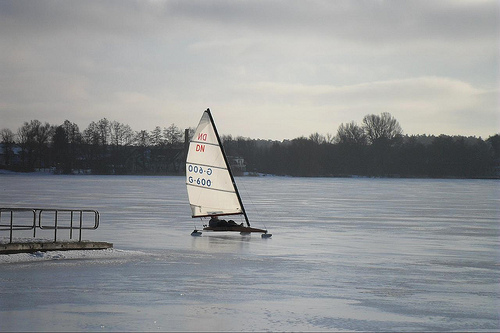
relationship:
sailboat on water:
[176, 106, 272, 243] [2, 170, 499, 332]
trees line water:
[1, 110, 406, 157] [2, 170, 499, 332]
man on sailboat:
[204, 212, 246, 228] [176, 106, 272, 243]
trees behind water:
[1, 110, 406, 157] [2, 170, 499, 332]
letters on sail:
[186, 163, 215, 189] [184, 107, 243, 215]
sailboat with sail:
[176, 106, 272, 243] [184, 107, 243, 215]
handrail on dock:
[0, 207, 102, 239] [1, 208, 113, 256]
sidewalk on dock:
[1, 243, 113, 251] [1, 208, 113, 256]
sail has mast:
[184, 107, 243, 215] [206, 110, 251, 229]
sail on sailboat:
[184, 107, 243, 215] [176, 106, 272, 243]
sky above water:
[1, 1, 498, 137] [2, 170, 499, 332]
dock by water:
[1, 208, 113, 256] [2, 170, 499, 332]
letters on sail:
[194, 133, 208, 154] [184, 107, 243, 215]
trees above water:
[1, 110, 406, 157] [2, 170, 499, 332]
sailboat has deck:
[176, 106, 272, 243] [190, 227, 270, 237]